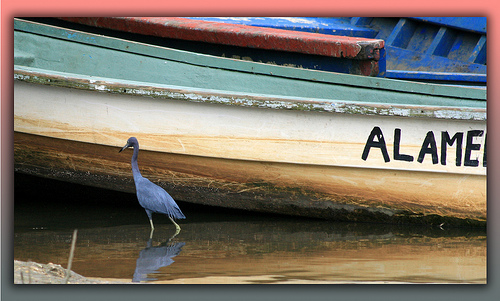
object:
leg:
[167, 213, 181, 228]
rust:
[57, 17, 385, 77]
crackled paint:
[12, 67, 487, 121]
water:
[14, 221, 351, 285]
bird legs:
[144, 208, 156, 230]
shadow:
[13, 171, 327, 232]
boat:
[13, 17, 487, 229]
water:
[326, 222, 487, 285]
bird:
[118, 137, 188, 230]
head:
[118, 137, 139, 154]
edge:
[386, 69, 487, 83]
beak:
[118, 144, 128, 153]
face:
[118, 137, 133, 153]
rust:
[213, 15, 332, 27]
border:
[0, 0, 500, 17]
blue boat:
[14, 17, 488, 87]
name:
[360, 126, 488, 167]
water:
[12, 170, 413, 226]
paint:
[13, 31, 487, 108]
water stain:
[12, 115, 366, 166]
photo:
[13, 16, 488, 284]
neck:
[131, 144, 143, 183]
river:
[13, 170, 487, 284]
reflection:
[131, 229, 185, 282]